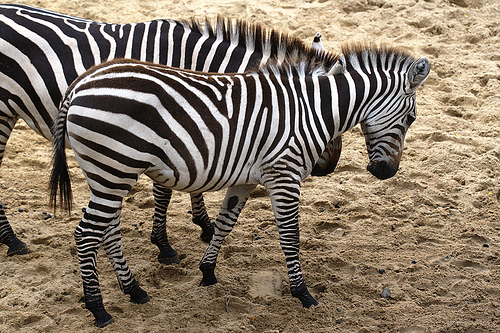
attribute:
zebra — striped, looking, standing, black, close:
[47, 43, 429, 329]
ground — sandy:
[1, 0, 498, 325]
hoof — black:
[92, 310, 114, 329]